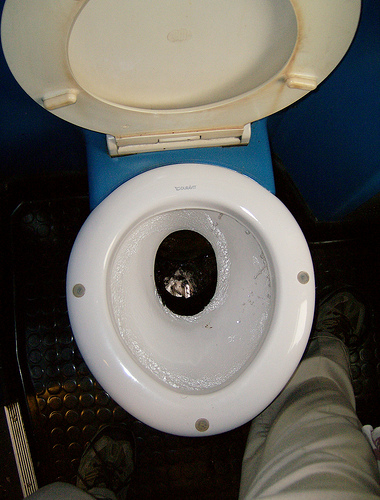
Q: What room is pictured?
A: It is a bathroom.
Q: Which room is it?
A: It is a bathroom.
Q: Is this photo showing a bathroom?
A: Yes, it is showing a bathroom.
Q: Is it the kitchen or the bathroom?
A: It is the bathroom.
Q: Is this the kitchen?
A: No, it is the bathroom.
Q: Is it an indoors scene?
A: Yes, it is indoors.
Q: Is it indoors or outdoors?
A: It is indoors.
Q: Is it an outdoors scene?
A: No, it is indoors.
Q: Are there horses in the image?
A: No, there are no horses.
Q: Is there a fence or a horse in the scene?
A: No, there are no horses or fences.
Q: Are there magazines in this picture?
A: No, there are no magazines.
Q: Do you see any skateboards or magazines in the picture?
A: No, there are no magazines or skateboards.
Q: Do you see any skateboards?
A: No, there are no skateboards.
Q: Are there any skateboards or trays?
A: No, there are no skateboards or trays.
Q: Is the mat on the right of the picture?
A: No, the mat is on the left of the image.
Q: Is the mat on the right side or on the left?
A: The mat is on the left of the image.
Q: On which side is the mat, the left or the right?
A: The mat is on the left of the image.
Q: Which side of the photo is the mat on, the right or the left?
A: The mat is on the left of the image.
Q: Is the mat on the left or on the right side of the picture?
A: The mat is on the left of the image.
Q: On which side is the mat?
A: The mat is on the left of the image.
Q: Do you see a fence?
A: No, there are no fences.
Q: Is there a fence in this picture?
A: No, there are no fences.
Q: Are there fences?
A: No, there are no fences.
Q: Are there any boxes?
A: No, there are no boxes.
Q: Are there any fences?
A: No, there are no fences.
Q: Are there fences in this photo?
A: No, there are no fences.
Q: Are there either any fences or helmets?
A: No, there are no fences or helmets.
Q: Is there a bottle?
A: No, there are no bottles.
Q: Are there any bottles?
A: No, there are no bottles.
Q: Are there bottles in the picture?
A: No, there are no bottles.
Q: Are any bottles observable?
A: No, there are no bottles.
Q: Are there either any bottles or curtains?
A: No, there are no bottles or curtains.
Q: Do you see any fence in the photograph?
A: No, there are no fences.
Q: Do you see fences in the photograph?
A: No, there are no fences.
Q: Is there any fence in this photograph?
A: No, there are no fences.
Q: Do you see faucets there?
A: No, there are no faucets.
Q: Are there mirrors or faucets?
A: No, there are no faucets or mirrors.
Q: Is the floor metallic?
A: Yes, the floor is metallic.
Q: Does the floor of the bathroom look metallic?
A: Yes, the floor is metallic.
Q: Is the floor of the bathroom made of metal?
A: Yes, the floor is made of metal.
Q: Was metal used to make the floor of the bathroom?
A: Yes, the floor is made of metal.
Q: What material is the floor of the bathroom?
A: The floor is made of metal.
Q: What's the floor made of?
A: The floor is made of metal.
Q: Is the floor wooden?
A: No, the floor is metallic.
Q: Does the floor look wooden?
A: No, the floor is metallic.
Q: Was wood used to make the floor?
A: No, the floor is made of metal.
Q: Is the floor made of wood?
A: No, the floor is made of metal.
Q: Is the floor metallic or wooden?
A: The floor is metallic.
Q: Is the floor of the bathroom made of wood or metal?
A: The floor is made of metal.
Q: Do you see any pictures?
A: No, there are no pictures.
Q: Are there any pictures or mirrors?
A: No, there are no pictures or mirrors.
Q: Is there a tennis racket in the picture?
A: No, there are no rackets.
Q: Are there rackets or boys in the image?
A: No, there are no rackets or boys.